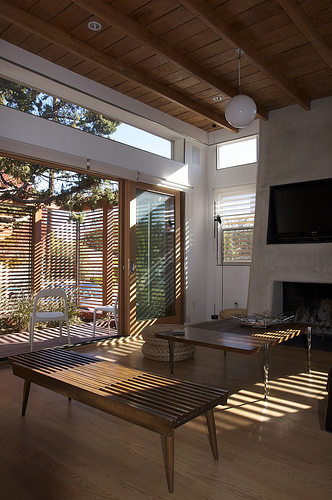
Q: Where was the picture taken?
A: Living room.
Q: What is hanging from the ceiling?
A: Light.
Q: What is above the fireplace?
A: TV.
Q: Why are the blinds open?
A: Let in light.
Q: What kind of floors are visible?
A: Wood.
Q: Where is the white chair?
A: Porch.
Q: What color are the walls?
A: White.